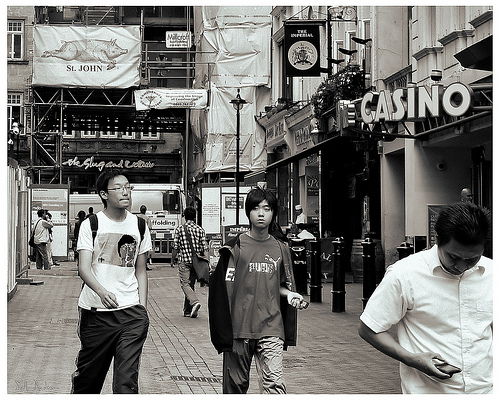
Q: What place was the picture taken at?
A: It was taken at the street.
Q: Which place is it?
A: It is a street.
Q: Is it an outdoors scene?
A: Yes, it is outdoors.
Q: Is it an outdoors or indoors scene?
A: It is outdoors.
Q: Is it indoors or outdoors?
A: It is outdoors.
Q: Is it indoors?
A: No, it is outdoors.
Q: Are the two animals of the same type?
A: No, they are seals and pigs.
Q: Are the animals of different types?
A: Yes, they are seals and pigs.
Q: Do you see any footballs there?
A: No, there are no footballs.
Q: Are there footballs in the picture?
A: No, there are no footballs.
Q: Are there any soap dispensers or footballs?
A: No, there are no footballs or soap dispensers.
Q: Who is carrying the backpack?
A: The man is carrying the backpack.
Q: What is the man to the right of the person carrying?
A: The man is carrying a backpack.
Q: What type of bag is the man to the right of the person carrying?
A: The man is carrying a backpack.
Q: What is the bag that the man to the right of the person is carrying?
A: The bag is a backpack.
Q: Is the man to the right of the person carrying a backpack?
A: Yes, the man is carrying a backpack.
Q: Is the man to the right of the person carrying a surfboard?
A: No, the man is carrying a backpack.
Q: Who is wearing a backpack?
A: The man is wearing a backpack.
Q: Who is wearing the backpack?
A: The man is wearing a backpack.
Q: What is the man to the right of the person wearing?
A: The man is wearing a backpack.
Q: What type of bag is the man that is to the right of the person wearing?
A: The man is wearing a backpack.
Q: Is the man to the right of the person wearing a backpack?
A: Yes, the man is wearing a backpack.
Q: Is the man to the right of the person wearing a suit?
A: No, the man is wearing a backpack.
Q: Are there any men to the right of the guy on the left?
A: Yes, there is a man to the right of the guy.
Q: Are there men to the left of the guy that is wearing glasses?
A: No, the man is to the right of the guy.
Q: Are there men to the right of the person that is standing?
A: Yes, there is a man to the right of the person.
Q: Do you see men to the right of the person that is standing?
A: Yes, there is a man to the right of the person.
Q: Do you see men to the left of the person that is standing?
A: No, the man is to the right of the person.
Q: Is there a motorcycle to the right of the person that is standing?
A: No, there is a man to the right of the person.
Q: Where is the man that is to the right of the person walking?
A: The man is walking on the street.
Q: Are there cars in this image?
A: No, there are no cars.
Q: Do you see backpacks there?
A: Yes, there is a backpack.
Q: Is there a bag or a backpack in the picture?
A: Yes, there is a backpack.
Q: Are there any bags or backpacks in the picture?
A: Yes, there is a backpack.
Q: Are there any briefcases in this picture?
A: No, there are no briefcases.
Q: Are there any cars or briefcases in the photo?
A: No, there are no briefcases or cars.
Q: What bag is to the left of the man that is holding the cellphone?
A: The bag is a backpack.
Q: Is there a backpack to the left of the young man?
A: Yes, there is a backpack to the left of the man.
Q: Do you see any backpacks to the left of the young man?
A: Yes, there is a backpack to the left of the man.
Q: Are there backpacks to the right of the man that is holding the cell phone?
A: No, the backpack is to the left of the man.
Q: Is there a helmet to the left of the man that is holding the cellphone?
A: No, there is a backpack to the left of the man.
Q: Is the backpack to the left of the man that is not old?
A: Yes, the backpack is to the left of the man.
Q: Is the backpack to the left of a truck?
A: No, the backpack is to the left of the man.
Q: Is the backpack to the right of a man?
A: No, the backpack is to the left of a man.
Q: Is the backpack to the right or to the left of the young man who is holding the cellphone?
A: The backpack is to the left of the man.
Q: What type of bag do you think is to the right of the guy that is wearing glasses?
A: The bag is a backpack.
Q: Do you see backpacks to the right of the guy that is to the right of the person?
A: Yes, there is a backpack to the right of the guy.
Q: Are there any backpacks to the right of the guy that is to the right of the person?
A: Yes, there is a backpack to the right of the guy.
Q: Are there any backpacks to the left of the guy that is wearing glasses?
A: No, the backpack is to the right of the guy.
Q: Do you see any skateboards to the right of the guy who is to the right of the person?
A: No, there is a backpack to the right of the guy.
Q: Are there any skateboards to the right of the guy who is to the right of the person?
A: No, there is a backpack to the right of the guy.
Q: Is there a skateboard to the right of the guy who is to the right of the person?
A: No, there is a backpack to the right of the guy.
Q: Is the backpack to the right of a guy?
A: Yes, the backpack is to the right of a guy.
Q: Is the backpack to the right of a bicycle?
A: No, the backpack is to the right of a guy.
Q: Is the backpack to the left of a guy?
A: No, the backpack is to the right of a guy.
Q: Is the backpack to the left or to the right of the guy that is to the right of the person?
A: The backpack is to the right of the guy.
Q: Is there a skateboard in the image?
A: No, there are no skateboards.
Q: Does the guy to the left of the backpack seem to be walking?
A: Yes, the guy is walking.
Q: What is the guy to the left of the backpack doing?
A: The guy is walking.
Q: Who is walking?
A: The guy is walking.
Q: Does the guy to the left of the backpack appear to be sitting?
A: No, the guy is walking.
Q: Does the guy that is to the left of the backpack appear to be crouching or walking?
A: The guy is walking.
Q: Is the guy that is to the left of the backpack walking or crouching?
A: The guy is walking.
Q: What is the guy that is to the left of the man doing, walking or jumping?
A: The guy is walking.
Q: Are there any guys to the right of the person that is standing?
A: Yes, there is a guy to the right of the person.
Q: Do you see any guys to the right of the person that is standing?
A: Yes, there is a guy to the right of the person.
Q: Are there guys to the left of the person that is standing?
A: No, the guy is to the right of the person.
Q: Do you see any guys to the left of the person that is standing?
A: No, the guy is to the right of the person.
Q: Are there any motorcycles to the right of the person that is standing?
A: No, there is a guy to the right of the person.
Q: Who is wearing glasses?
A: The guy is wearing glasses.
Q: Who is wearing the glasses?
A: The guy is wearing glasses.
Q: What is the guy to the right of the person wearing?
A: The guy is wearing glasses.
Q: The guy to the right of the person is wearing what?
A: The guy is wearing glasses.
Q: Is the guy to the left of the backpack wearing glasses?
A: Yes, the guy is wearing glasses.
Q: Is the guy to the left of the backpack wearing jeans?
A: No, the guy is wearing glasses.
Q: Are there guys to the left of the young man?
A: Yes, there is a guy to the left of the man.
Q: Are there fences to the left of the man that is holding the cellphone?
A: No, there is a guy to the left of the man.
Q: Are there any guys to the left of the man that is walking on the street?
A: Yes, there is a guy to the left of the man.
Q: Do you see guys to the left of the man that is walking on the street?
A: Yes, there is a guy to the left of the man.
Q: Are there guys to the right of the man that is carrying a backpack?
A: No, the guy is to the left of the man.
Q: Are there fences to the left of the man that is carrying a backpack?
A: No, there is a guy to the left of the man.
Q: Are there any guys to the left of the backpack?
A: Yes, there is a guy to the left of the backpack.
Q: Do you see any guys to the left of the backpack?
A: Yes, there is a guy to the left of the backpack.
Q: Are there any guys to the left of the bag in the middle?
A: Yes, there is a guy to the left of the backpack.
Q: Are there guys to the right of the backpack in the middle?
A: No, the guy is to the left of the backpack.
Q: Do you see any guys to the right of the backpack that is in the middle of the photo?
A: No, the guy is to the left of the backpack.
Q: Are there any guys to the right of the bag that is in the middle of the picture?
A: No, the guy is to the left of the backpack.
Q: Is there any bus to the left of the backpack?
A: No, there is a guy to the left of the backpack.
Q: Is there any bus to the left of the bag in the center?
A: No, there is a guy to the left of the backpack.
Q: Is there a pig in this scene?
A: Yes, there is a pig.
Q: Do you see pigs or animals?
A: Yes, there is a pig.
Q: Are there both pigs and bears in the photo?
A: No, there is a pig but no bears.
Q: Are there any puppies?
A: No, there are no puppies.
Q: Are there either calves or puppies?
A: No, there are no puppies or calves.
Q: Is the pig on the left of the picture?
A: Yes, the pig is on the left of the image.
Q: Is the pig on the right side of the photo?
A: No, the pig is on the left of the image.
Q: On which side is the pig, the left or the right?
A: The pig is on the left of the image.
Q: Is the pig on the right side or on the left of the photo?
A: The pig is on the left of the image.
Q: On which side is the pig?
A: The pig is on the left of the image.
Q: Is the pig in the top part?
A: Yes, the pig is in the top of the image.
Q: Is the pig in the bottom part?
A: No, the pig is in the top of the image.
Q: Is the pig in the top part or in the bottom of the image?
A: The pig is in the top of the image.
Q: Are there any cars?
A: No, there are no cars.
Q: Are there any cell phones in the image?
A: Yes, there is a cell phone.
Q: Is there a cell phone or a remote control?
A: Yes, there is a cell phone.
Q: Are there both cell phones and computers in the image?
A: No, there is a cell phone but no computers.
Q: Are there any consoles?
A: No, there are no consoles.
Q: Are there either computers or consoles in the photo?
A: No, there are no consoles or computers.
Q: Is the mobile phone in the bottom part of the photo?
A: Yes, the mobile phone is in the bottom of the image.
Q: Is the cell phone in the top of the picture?
A: No, the cell phone is in the bottom of the image.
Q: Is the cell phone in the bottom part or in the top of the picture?
A: The cell phone is in the bottom of the image.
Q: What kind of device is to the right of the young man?
A: The device is a cell phone.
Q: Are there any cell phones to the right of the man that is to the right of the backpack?
A: Yes, there is a cell phone to the right of the man.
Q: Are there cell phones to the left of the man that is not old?
A: No, the cell phone is to the right of the man.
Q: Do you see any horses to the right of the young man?
A: No, there is a cell phone to the right of the man.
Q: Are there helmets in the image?
A: No, there are no helmets.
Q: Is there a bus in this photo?
A: No, there are no buses.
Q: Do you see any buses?
A: No, there are no buses.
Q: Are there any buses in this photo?
A: No, there are no buses.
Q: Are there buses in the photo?
A: No, there are no buses.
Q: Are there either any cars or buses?
A: No, there are no buses or cars.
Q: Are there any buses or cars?
A: No, there are no buses or cars.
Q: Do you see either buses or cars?
A: No, there are no buses or cars.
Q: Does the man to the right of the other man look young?
A: Yes, the man is young.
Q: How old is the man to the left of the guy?
A: The man is young.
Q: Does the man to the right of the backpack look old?
A: No, the man is young.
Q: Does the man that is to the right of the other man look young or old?
A: The man is young.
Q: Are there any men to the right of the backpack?
A: Yes, there is a man to the right of the backpack.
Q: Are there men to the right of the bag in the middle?
A: Yes, there is a man to the right of the backpack.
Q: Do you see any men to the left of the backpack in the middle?
A: No, the man is to the right of the backpack.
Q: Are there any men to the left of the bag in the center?
A: No, the man is to the right of the backpack.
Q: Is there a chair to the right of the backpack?
A: No, there is a man to the right of the backpack.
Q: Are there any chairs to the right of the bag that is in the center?
A: No, there is a man to the right of the backpack.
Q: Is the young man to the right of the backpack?
A: Yes, the man is to the right of the backpack.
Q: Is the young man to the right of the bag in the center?
A: Yes, the man is to the right of the backpack.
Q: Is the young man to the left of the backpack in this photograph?
A: No, the man is to the right of the backpack.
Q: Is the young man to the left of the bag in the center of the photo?
A: No, the man is to the right of the backpack.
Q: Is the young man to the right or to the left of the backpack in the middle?
A: The man is to the right of the backpack.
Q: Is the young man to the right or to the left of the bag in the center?
A: The man is to the right of the backpack.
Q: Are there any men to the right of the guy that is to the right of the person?
A: Yes, there is a man to the right of the guy.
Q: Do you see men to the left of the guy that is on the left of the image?
A: No, the man is to the right of the guy.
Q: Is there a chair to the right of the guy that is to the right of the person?
A: No, there is a man to the right of the guy.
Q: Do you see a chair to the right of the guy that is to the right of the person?
A: No, there is a man to the right of the guy.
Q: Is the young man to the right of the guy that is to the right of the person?
A: Yes, the man is to the right of the guy.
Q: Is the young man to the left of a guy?
A: No, the man is to the right of a guy.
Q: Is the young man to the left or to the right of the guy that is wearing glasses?
A: The man is to the right of the guy.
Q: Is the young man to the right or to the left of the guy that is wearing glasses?
A: The man is to the right of the guy.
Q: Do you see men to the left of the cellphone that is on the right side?
A: Yes, there is a man to the left of the cellphone.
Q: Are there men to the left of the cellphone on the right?
A: Yes, there is a man to the left of the cellphone.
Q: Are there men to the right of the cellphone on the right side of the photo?
A: No, the man is to the left of the mobile phone.